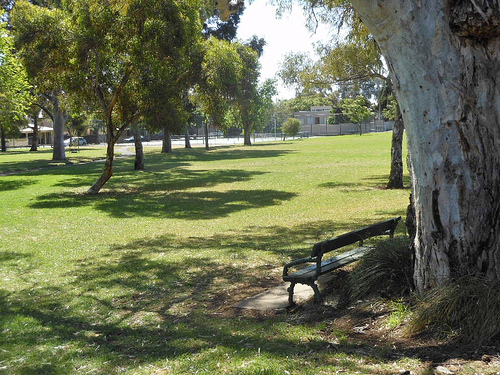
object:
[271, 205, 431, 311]
bench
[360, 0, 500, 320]
bark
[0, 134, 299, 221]
shadows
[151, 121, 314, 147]
court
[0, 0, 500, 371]
park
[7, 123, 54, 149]
home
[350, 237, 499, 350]
grass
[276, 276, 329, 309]
footrest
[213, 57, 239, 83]
leaves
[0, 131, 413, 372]
grass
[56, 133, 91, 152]
car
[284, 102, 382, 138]
building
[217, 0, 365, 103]
sky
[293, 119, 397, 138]
fence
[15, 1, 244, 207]
tree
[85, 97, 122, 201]
trunk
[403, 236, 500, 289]
base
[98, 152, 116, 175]
curving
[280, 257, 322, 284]
arm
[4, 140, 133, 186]
walkway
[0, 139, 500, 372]
city park